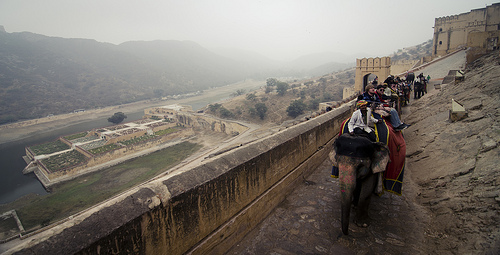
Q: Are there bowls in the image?
A: No, there are no bowls.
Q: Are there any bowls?
A: No, there are no bowls.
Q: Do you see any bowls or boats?
A: No, there are no bowls or boats.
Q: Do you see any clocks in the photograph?
A: No, there are no clocks.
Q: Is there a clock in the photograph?
A: No, there are no clocks.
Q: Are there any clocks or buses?
A: No, there are no clocks or buses.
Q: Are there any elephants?
A: Yes, there is an elephant.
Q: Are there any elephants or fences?
A: Yes, there is an elephant.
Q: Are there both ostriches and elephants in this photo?
A: No, there is an elephant but no ostriches.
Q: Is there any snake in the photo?
A: No, there are no snakes.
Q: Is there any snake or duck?
A: No, there are no snakes or ducks.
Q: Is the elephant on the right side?
A: Yes, the elephant is on the right of the image.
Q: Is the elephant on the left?
A: No, the elephant is on the right of the image.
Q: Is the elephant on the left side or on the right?
A: The elephant is on the right of the image.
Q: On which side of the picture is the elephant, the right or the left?
A: The elephant is on the right of the image.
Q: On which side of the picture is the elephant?
A: The elephant is on the right of the image.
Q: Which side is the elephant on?
A: The elephant is on the right of the image.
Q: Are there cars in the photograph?
A: No, there are no cars.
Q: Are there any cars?
A: No, there are no cars.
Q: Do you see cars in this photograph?
A: No, there are no cars.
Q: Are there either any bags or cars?
A: No, there are no cars or bags.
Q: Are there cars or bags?
A: No, there are no cars or bags.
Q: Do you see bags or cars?
A: No, there are no cars or bags.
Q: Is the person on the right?
A: Yes, the person is on the right of the image.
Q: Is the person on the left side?
A: No, the person is on the right of the image.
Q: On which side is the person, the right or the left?
A: The person is on the right of the image.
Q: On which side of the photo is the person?
A: The person is on the right of the image.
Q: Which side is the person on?
A: The person is on the right of the image.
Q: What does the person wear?
A: The person wears a jacket.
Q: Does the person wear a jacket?
A: Yes, the person wears a jacket.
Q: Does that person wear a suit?
A: No, the person wears a jacket.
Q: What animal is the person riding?
A: The person is riding an elephant.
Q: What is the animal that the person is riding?
A: The animal is an elephant.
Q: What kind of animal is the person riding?
A: The person is riding an elephant.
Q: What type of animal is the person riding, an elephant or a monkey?
A: The person is riding an elephant.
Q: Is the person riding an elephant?
A: Yes, the person is riding an elephant.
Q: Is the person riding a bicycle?
A: No, the person is riding an elephant.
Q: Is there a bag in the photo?
A: No, there are no bags.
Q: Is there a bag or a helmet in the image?
A: No, there are no bags or helmets.